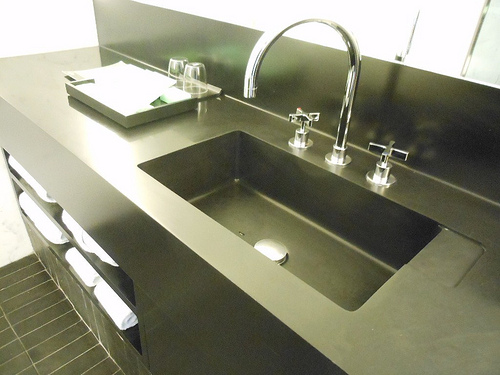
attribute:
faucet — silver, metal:
[233, 2, 373, 159]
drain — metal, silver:
[257, 214, 302, 268]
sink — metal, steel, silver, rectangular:
[85, 57, 457, 326]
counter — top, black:
[406, 257, 499, 333]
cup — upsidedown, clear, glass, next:
[158, 44, 217, 109]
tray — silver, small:
[54, 51, 197, 141]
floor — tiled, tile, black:
[38, 339, 65, 368]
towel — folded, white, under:
[13, 190, 58, 256]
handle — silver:
[271, 100, 344, 152]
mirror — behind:
[387, 13, 450, 63]